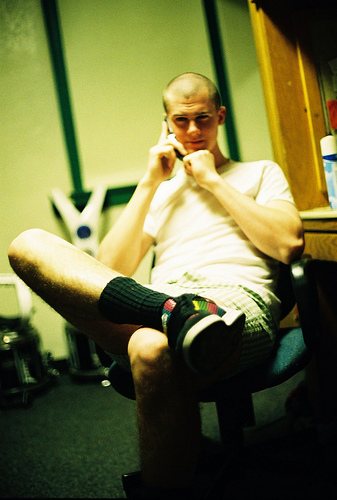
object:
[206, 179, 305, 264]
arm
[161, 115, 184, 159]
cell phone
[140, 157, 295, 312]
shirt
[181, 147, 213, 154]
chin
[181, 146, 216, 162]
knuckles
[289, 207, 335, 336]
desk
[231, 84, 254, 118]
ground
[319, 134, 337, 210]
bottle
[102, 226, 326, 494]
chair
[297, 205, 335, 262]
wood table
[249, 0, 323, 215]
wood panel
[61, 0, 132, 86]
wall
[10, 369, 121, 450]
green carpet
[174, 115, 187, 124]
eye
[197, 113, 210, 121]
eye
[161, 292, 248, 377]
shoe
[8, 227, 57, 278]
knee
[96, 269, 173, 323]
sock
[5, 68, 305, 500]
man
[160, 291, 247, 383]
black shoe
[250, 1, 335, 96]
shadow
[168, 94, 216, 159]
face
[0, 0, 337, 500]
room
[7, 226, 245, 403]
legs